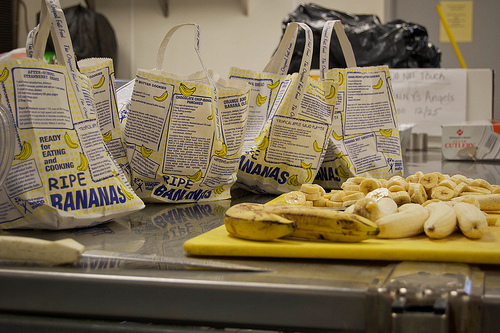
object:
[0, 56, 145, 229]
bag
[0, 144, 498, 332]
table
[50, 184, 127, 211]
writing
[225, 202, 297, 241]
banana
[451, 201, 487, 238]
banana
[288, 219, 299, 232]
tip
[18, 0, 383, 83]
wall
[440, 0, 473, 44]
notice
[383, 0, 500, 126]
door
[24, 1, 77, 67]
handle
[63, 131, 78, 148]
banana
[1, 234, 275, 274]
knife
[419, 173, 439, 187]
banana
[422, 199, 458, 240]
banana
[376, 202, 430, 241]
banana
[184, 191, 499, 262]
cutting board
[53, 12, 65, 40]
writing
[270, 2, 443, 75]
bag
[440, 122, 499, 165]
box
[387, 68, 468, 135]
paper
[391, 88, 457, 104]
writing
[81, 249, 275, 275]
blade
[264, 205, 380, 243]
banana